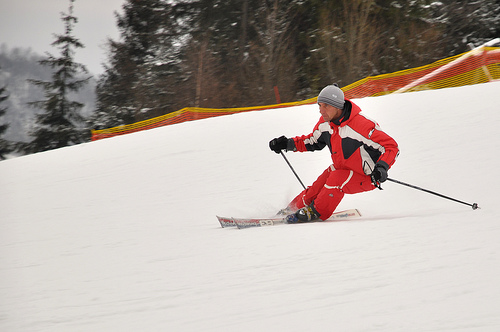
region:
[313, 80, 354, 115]
He has a grey hat.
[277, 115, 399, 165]
His jacket is red.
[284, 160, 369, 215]
His pants are red.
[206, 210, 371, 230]
His skies arered and grey.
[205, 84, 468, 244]
He has two poles.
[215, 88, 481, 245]
The poles are black.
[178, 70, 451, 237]
He is skiing.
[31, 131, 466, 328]
The ground is snow covered.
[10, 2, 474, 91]
The trees are leafy.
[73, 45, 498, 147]
The fence is yellow and orange.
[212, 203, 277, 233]
Part of athletic person's skis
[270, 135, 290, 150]
Hand of athletic skier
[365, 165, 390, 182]
Hand of athletic skier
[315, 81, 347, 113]
Head of athletic skier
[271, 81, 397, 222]
Athletic skier on slope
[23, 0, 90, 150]
Nice evergreen tree on slope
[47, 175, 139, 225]
Part of snowy slope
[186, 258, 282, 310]
Part of snowy slope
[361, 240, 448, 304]
Part pf snowy slope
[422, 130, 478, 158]
Part of snowy slope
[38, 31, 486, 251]
a man skiing down a hillside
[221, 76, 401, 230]
a man wearing a ski suit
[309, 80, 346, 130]
a man wearing a gray cap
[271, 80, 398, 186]
a man wearing a ski jacket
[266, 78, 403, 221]
a man wearing ski pants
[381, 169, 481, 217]
a long black ski pole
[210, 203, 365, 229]
a pair of snow skis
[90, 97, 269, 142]
an orange and red snow fence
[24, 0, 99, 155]
a tall conifer tree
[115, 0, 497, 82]
several trees along a ski slope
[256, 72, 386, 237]
skier on hill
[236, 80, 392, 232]
skier wearing red black and white clothing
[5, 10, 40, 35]
white clouds in blue sky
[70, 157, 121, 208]
white snow on hill side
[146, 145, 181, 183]
white snow on hill side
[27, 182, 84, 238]
white snow on hill side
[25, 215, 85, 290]
white snow on hill side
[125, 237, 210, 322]
white snow on hill side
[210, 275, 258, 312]
white snow on hill side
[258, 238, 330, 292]
white snow on hill side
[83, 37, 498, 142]
A yellow and red net.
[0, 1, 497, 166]
Evergreen trees.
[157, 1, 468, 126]
Trees without any leaves.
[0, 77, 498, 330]
Snow covering the ground.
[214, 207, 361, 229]
A pair of skis.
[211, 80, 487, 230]
A man skiing.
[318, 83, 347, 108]
A grey tobogan.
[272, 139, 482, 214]
Black ski poles.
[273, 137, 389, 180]
Black ski gloves.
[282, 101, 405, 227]
A red, white, and black ski suit.